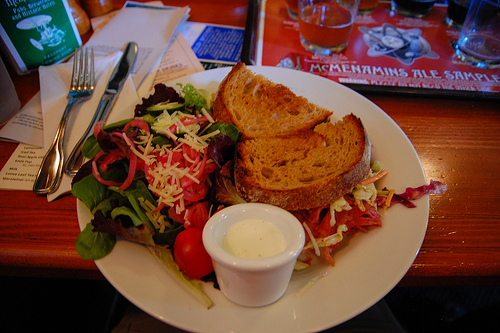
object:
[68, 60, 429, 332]
plate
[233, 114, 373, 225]
sandwich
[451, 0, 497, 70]
glass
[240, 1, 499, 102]
tray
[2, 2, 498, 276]
table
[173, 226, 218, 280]
cherry tomato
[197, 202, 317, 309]
container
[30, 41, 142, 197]
silverware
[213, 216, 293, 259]
salad dressing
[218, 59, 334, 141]
toast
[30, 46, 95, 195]
fork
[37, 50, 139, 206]
napkin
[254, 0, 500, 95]
sample menu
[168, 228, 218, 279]
tomato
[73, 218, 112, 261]
lettuce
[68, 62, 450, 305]
food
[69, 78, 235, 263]
salad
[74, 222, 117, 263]
vegetable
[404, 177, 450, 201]
meat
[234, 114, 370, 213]
bread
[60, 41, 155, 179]
knife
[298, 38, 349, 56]
bottom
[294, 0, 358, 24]
glass